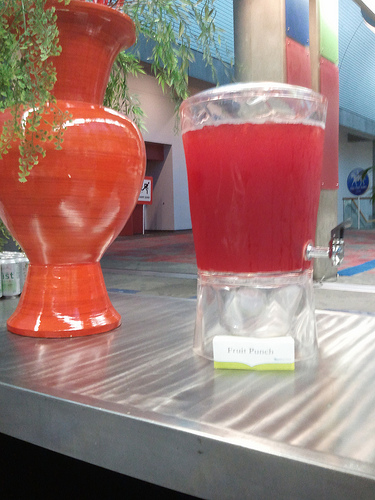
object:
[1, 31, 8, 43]
leaves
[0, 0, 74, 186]
plant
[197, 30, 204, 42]
leaf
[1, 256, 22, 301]
beverages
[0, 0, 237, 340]
planter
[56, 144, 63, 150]
leaf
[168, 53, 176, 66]
leaf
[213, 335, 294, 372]
card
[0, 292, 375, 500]
table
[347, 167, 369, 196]
painting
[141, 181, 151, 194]
figure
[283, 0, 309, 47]
tiles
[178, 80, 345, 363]
container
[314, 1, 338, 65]
retangles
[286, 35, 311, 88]
column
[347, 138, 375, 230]
wall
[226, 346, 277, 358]
fruit punch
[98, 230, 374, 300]
carpet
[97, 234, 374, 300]
ground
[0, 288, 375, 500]
counter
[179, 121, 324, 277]
drinks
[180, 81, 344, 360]
dispenser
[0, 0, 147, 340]
pot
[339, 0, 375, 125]
wall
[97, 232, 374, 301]
floor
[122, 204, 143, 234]
door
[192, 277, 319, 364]
glass